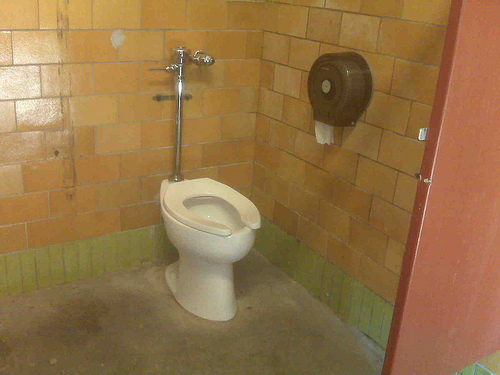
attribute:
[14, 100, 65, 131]
tile — rectangle, brown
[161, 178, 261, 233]
toilet plate — white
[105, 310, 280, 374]
toilet floor — brown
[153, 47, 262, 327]
toilet — white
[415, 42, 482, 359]
door — red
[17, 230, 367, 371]
floor — concrete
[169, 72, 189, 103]
pipe — shiny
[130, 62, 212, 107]
handle — chrome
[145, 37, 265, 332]
toilet — porcelain, white, public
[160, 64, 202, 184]
pole — metal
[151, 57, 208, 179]
pipe — stainless steel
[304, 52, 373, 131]
holder — black 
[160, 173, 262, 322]
toilet — white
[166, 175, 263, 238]
toilet seat — white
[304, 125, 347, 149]
tissue paper — white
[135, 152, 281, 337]
toilet — clean, white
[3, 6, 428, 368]
wall — tiled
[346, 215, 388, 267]
tile — brown, rectangle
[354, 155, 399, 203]
tile — brown, rectangle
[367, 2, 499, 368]
door — red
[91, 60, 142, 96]
wall tile — brown, rectangle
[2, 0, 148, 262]
wall — brown, tiled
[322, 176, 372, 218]
tile — brown, rectangular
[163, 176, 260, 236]
seat — down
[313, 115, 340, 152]
tissue paper — white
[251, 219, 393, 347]
bottom — green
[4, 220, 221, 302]
bottom — tile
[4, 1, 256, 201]
wall — tiled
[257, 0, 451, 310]
wall — beige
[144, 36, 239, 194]
water pump — metallic